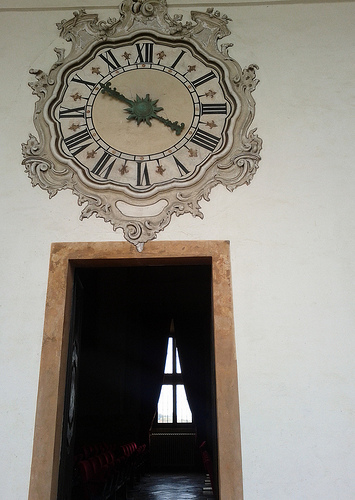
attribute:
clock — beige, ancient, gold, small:
[18, 0, 265, 253]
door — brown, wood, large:
[23, 239, 243, 499]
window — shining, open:
[153, 338, 196, 429]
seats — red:
[76, 440, 145, 492]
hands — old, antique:
[99, 83, 185, 134]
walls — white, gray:
[2, 1, 349, 500]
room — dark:
[64, 261, 217, 495]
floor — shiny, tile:
[115, 450, 206, 497]